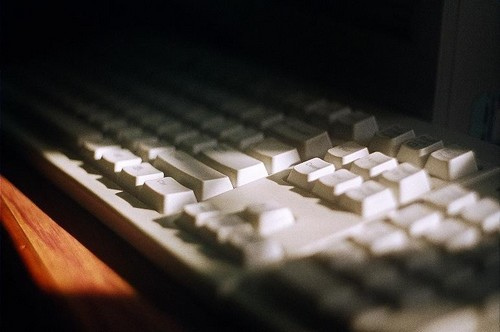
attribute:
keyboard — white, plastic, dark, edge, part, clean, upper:
[50, 57, 470, 328]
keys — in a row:
[83, 75, 199, 141]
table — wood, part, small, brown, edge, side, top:
[33, 219, 122, 268]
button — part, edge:
[235, 154, 271, 176]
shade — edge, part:
[443, 54, 478, 120]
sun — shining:
[247, 174, 309, 188]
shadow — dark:
[176, 8, 204, 23]